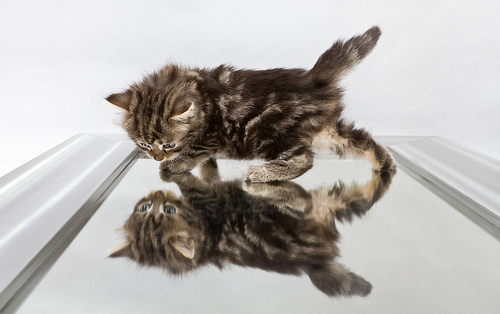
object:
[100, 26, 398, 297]
cat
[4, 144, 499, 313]
mirror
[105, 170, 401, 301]
reflection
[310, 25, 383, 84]
tail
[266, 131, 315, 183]
leg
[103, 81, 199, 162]
head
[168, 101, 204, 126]
ear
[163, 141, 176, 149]
eye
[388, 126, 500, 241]
edge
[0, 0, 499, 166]
wall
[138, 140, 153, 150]
eye